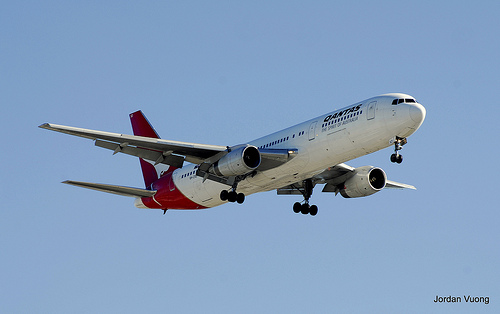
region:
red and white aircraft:
[35, 81, 425, 215]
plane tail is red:
[125, 110, 157, 136]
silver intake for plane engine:
[219, 146, 261, 177]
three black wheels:
[292, 201, 317, 216]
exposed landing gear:
[221, 174, 246, 207]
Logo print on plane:
[319, 107, 365, 126]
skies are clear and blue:
[104, 14, 322, 95]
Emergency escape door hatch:
[365, 100, 375, 120]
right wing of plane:
[35, 115, 225, 160]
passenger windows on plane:
[264, 135, 309, 147]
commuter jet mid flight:
[48, 0, 467, 245]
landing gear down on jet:
[34, 63, 437, 272]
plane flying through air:
[0, 14, 497, 309]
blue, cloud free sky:
[0, 0, 495, 308]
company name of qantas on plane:
[34, 70, 432, 240]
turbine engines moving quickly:
[198, 118, 383, 212]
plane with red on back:
[2, 8, 442, 248]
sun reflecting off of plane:
[0, 17, 460, 264]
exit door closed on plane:
[40, 68, 440, 219]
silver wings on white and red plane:
[36, 6, 458, 284]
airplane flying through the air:
[35, 78, 444, 224]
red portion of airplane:
[121, 107, 201, 217]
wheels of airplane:
[217, 144, 411, 221]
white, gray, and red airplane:
[42, 70, 451, 230]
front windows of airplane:
[389, 98, 417, 108]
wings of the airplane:
[42, 118, 419, 219]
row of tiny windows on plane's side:
[166, 132, 315, 187]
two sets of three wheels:
[220, 187, 322, 218]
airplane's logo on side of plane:
[311, 98, 363, 135]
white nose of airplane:
[396, 100, 433, 133]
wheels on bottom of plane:
[215, 184, 252, 206]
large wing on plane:
[38, 111, 297, 196]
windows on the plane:
[320, 120, 340, 130]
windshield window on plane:
[391, 94, 419, 109]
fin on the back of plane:
[57, 169, 167, 215]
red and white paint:
[160, 177, 192, 199]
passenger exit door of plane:
[304, 118, 317, 145]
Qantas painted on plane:
[317, 100, 364, 121]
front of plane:
[381, 84, 428, 170]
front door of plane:
[365, 97, 382, 122]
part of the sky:
[400, 221, 415, 231]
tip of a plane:
[409, 113, 411, 153]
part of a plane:
[343, 143, 352, 157]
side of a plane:
[264, 133, 279, 157]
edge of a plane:
[217, 129, 233, 165]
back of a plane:
[154, 183, 179, 205]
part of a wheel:
[310, 202, 334, 208]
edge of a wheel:
[229, 174, 268, 206]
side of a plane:
[313, 128, 321, 156]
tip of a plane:
[412, 106, 416, 133]